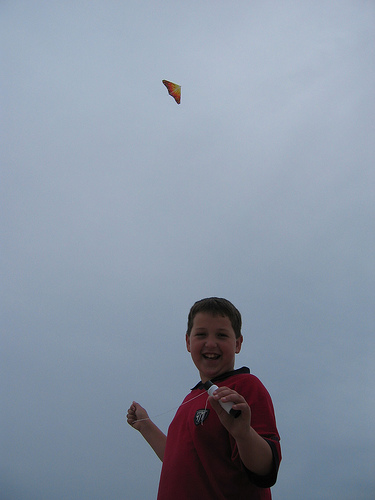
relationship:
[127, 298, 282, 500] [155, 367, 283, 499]
boy in shirt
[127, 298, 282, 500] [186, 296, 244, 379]
boy has head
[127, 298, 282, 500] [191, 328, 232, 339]
boy has eyes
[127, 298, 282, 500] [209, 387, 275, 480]
boy has hand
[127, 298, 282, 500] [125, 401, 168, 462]
boy has hand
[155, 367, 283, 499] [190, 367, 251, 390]
shirt has collar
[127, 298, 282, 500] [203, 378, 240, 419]
boy has spool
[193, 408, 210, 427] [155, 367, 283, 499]
logo on shirt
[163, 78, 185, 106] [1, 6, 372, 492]
kite in sky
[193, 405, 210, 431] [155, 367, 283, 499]
logo on shirt